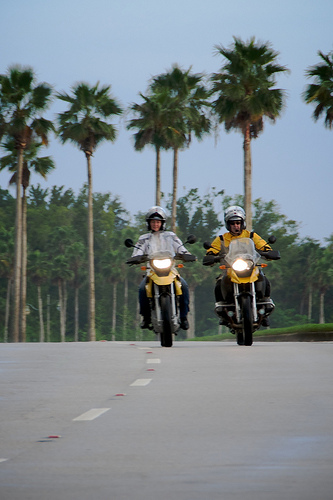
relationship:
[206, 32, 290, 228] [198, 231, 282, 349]
tree behind motorcycle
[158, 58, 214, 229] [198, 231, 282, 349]
tree behind motorcycle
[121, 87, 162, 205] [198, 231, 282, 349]
tree behind motorcycle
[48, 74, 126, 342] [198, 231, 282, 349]
tree behind motorcycle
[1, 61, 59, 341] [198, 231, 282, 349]
tree behind motorcycle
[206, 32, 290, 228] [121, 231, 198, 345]
tree behind motorcycle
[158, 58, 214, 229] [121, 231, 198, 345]
tree behind motorcycle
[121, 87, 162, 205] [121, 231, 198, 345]
tree behind motorcycle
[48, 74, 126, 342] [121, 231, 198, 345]
tree behind motorcycle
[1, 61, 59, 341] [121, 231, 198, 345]
tree behind motorcycle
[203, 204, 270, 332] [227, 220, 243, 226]
man wearing sunglasses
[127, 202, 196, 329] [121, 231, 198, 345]
person driving motorcycle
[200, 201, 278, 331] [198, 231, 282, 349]
man riding motorcycle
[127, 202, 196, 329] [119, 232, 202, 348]
person riding motorcycle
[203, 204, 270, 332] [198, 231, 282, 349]
man on motorcycle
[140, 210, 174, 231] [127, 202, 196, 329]
helmet on person